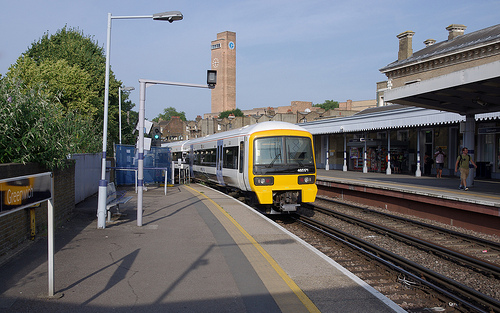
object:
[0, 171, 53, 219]
sign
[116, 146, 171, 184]
fence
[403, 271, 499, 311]
gravel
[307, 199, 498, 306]
train tracks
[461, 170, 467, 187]
legs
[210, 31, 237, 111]
building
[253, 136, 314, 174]
front windshield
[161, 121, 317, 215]
train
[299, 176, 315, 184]
headlight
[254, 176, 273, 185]
headlight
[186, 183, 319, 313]
line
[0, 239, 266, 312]
concrete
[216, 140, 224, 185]
door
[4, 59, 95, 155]
tree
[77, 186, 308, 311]
road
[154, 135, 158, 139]
light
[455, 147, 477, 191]
man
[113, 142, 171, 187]
portable bathrooms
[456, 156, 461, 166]
arm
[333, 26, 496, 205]
station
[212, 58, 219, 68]
clock